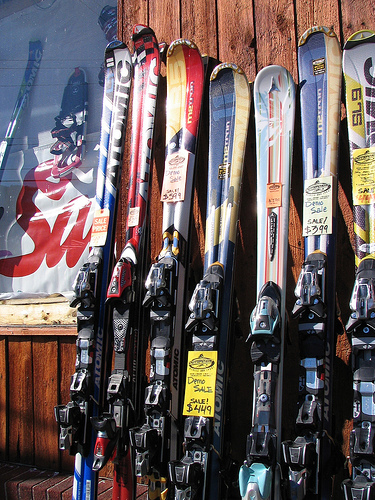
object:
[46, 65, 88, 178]
snowshoe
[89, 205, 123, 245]
675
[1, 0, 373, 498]
wall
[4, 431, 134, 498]
brick trim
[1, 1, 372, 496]
building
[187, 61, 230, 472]
matching skis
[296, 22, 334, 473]
matching skis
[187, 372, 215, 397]
lettering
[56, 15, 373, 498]
remotecontrol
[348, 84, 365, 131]
675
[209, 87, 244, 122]
11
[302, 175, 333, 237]
tag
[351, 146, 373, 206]
tag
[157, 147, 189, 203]
tag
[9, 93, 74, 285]
white sign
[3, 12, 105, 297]
window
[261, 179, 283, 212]
price tag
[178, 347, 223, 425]
tag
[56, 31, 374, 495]
skies lined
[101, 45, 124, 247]
ski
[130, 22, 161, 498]
stripes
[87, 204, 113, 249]
baseball hat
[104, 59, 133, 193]
atomic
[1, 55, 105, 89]
utility lines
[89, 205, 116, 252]
price tag